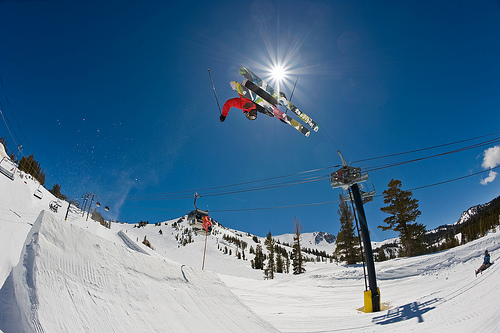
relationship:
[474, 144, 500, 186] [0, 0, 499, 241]
cloud in sky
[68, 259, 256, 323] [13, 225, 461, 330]
snow covering ground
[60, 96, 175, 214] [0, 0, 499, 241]
cloud hanging in sky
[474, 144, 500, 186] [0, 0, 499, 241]
cloud hanging in sky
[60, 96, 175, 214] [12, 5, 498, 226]
cloud hanging in sky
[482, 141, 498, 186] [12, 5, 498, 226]
cloud hanging in sky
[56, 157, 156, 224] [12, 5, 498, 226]
cloud hanging in sky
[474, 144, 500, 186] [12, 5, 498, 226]
cloud hanging in sky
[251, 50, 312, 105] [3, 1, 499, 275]
sun in sky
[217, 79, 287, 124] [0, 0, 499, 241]
person against sky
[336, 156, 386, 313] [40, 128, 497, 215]
pole supports ski lift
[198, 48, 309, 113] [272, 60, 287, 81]
lens flare caused by sun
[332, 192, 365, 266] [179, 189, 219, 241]
tree alongside ski lift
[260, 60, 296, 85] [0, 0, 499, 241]
sun in sky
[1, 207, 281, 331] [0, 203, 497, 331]
ski ramp in snow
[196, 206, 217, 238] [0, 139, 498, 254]
person in ski lift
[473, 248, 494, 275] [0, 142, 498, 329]
person sitting in snow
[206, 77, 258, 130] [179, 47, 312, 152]
person doing tricks on board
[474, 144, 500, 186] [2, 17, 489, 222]
cloud in sky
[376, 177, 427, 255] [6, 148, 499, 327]
tree in resort area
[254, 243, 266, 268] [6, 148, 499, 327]
tree in resort area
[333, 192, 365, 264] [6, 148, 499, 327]
tree in resort area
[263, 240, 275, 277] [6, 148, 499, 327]
tree in resort area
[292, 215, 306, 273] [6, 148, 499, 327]
tree in resort area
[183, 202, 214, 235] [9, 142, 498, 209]
chair on ski lift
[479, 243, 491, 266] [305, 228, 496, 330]
person on slope